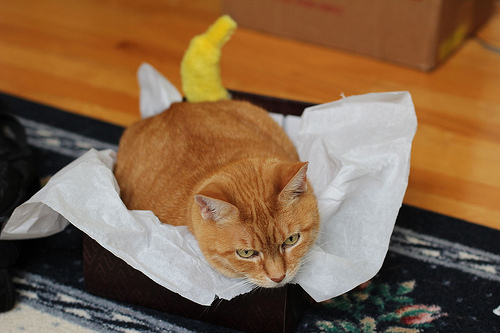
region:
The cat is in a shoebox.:
[41, 15, 396, 327]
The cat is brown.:
[120, 99, 342, 284]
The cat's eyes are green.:
[217, 230, 310, 266]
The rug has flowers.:
[318, 264, 460, 331]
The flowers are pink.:
[397, 282, 450, 329]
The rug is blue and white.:
[315, 209, 497, 330]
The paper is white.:
[284, 67, 427, 308]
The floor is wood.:
[268, 44, 498, 212]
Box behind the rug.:
[236, 0, 491, 62]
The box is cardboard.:
[252, 7, 444, 72]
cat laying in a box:
[57, 64, 392, 322]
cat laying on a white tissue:
[1, 32, 416, 329]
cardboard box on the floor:
[226, 4, 498, 78]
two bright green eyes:
[229, 232, 308, 264]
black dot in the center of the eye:
[289, 234, 297, 246]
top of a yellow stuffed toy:
[167, 5, 239, 87]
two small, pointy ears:
[191, 165, 321, 228]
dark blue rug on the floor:
[4, 86, 491, 332]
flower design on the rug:
[334, 278, 451, 331]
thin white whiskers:
[214, 267, 269, 304]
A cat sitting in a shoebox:
[87, 76, 370, 322]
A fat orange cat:
[82, 84, 332, 292]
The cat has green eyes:
[236, 231, 310, 263]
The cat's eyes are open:
[229, 230, 310, 264]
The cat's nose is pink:
[271, 275, 291, 287]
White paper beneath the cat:
[62, 118, 424, 312]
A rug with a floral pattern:
[348, 268, 463, 331]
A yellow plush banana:
[179, 7, 241, 107]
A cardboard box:
[238, 0, 454, 78]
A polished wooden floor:
[27, 10, 479, 177]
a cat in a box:
[19, 63, 451, 323]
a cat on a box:
[89, 67, 425, 329]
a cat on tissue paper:
[12, 15, 399, 327]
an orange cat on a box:
[61, 20, 431, 331]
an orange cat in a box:
[66, 61, 469, 331]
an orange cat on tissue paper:
[27, 27, 447, 331]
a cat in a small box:
[19, 57, 435, 332]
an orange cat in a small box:
[85, 35, 426, 331]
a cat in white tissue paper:
[29, 6, 411, 321]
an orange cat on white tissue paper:
[19, 46, 472, 328]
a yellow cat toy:
[165, 2, 250, 112]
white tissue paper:
[301, 80, 444, 305]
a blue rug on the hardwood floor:
[381, 207, 469, 330]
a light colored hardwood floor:
[36, 26, 115, 113]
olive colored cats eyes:
[217, 227, 313, 282]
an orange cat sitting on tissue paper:
[97, 77, 355, 304]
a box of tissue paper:
[67, 208, 335, 331]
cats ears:
[158, 135, 339, 255]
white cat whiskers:
[212, 262, 263, 313]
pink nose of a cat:
[239, 263, 300, 303]